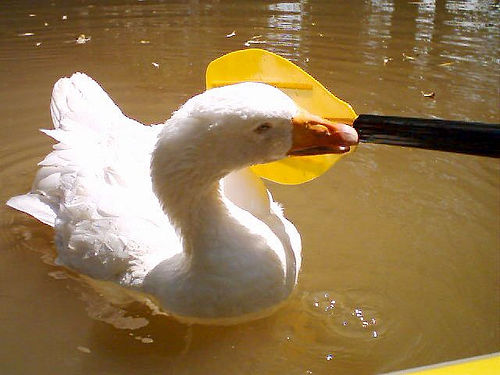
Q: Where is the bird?
A: In the water.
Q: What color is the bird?
A: White.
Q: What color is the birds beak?
A: Orange.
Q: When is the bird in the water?
A: Daytime.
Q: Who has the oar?
A: Boater.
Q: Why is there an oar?
A: To row the boat.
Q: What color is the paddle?
A: Yellow.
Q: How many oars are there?
A: One.